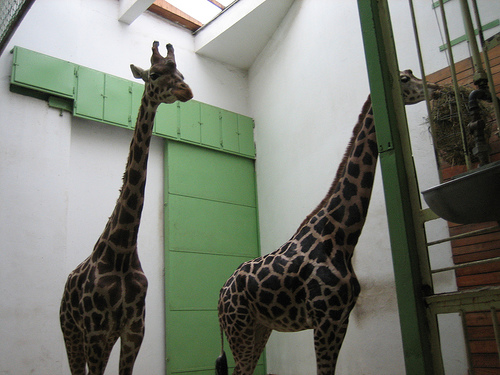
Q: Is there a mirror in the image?
A: No, there are no mirrors.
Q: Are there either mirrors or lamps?
A: No, there are no mirrors or lamps.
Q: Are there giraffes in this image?
A: Yes, there is a giraffe.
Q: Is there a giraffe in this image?
A: Yes, there is a giraffe.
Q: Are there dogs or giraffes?
A: Yes, there is a giraffe.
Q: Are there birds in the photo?
A: No, there are no birds.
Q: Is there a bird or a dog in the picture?
A: No, there are no birds or dogs.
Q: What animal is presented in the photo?
A: The animal is a giraffe.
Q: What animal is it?
A: The animal is a giraffe.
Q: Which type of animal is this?
A: This is a giraffe.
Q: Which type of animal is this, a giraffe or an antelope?
A: This is a giraffe.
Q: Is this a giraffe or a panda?
A: This is a giraffe.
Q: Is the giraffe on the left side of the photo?
A: Yes, the giraffe is on the left of the image.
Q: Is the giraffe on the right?
A: No, the giraffe is on the left of the image.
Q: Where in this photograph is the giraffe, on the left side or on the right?
A: The giraffe is on the left of the image.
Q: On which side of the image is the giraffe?
A: The giraffe is on the left of the image.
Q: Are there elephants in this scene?
A: No, there are no elephants.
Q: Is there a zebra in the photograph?
A: No, there are no zebras.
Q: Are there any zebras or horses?
A: No, there are no zebras or horses.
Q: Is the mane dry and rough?
A: Yes, the mane is dry and rough.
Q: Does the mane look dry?
A: Yes, the mane is dry.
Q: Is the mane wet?
A: No, the mane is dry.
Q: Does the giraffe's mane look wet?
A: No, the mane is dry.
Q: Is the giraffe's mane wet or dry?
A: The mane is dry.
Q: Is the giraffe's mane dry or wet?
A: The mane is dry.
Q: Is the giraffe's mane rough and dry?
A: Yes, the mane is rough and dry.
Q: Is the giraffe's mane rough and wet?
A: No, the mane is rough but dry.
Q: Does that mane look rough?
A: Yes, the mane is rough.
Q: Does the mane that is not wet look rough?
A: Yes, the mane is rough.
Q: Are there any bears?
A: No, there are no bears.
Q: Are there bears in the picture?
A: No, there are no bears.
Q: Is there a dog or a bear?
A: No, there are no bears or dogs.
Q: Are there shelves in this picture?
A: No, there are no shelves.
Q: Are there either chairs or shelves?
A: No, there are no shelves or chairs.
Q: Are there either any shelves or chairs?
A: No, there are no shelves or chairs.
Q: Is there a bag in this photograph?
A: No, there are no bags.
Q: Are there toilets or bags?
A: No, there are no bags or toilets.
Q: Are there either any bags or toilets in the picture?
A: No, there are no bags or toilets.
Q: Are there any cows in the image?
A: No, there are no cows.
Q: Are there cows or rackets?
A: No, there are no cows or rackets.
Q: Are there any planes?
A: No, there are no planes.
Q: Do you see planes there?
A: No, there are no planes.